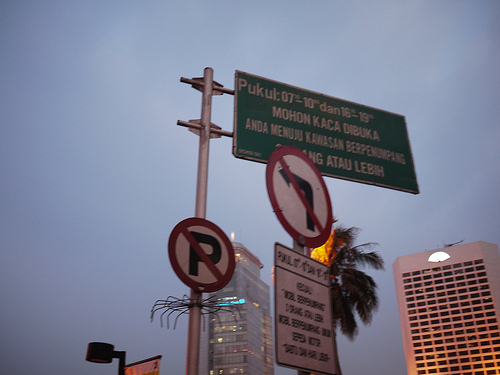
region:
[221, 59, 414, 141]
A green sign with words that are foreign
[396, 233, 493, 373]
A building with many floors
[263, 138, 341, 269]
No left turns here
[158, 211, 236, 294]
No parking sign here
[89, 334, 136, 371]
A street light that is dark now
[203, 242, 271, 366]
A very tall building that has many lights inside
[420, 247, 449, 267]
A logo on a building that is lit up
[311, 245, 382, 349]
A palm tree that is near a light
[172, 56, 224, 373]
A metal pole that is holding two signs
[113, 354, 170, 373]
A banner hanging from a pole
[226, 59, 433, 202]
green sign with white writing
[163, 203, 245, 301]
sign shaped like circle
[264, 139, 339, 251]
no left turn sign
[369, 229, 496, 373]
tall building in distance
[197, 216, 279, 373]
tall building with windows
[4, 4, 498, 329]
cloudy sky over buildings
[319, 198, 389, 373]
palm tree in front of building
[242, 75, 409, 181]
white writing on green sign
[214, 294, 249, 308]
blue light in building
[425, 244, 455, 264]
light on building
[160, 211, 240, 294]
Red and white no parking sign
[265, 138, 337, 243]
red and white no left turns sign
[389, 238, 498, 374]
tall white building in the city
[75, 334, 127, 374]
black street light pole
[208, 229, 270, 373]
clear tall building with windows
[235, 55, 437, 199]
green street sign in foreign language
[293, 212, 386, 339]
green palm tree in the city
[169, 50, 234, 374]
silver pole to hold all the signs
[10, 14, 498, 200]
gray and cloudy sky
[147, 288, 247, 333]
metal contraption to keep signs from falling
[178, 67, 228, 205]
this is a post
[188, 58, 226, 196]
the post is thin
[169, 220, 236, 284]
this is a red post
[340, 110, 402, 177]
the post is green in color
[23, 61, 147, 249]
the sky is clear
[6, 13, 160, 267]
the sky is grey in color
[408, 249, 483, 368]
this is a building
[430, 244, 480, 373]
the building is tall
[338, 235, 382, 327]
the leaves are green in color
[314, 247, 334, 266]
the light is on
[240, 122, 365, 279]
large no turning sign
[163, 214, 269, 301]
large no parking sign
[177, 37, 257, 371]
signs on a metal pole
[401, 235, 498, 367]
building with some windows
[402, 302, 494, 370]
building is well lit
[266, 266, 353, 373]
black writing on a white sign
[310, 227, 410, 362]
green palm leaves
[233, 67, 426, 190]
white lettering on a green sign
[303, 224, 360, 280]
light behind the sign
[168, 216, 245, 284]
sign is red and white